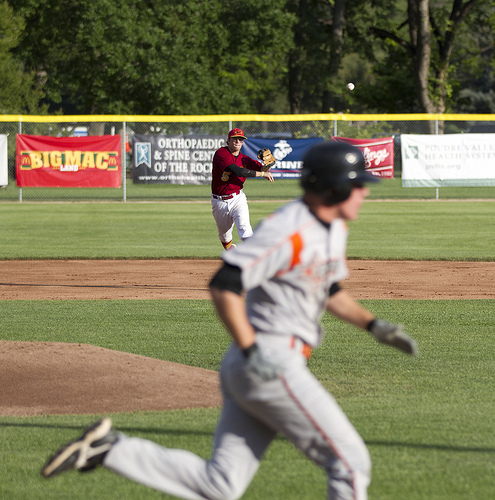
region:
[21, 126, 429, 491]
the baseball player is running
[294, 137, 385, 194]
the baseball player is wearing a baseball cap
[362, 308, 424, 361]
the man is wearing a glove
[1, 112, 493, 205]
a barrier behind the players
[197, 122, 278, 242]
the man is running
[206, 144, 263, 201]
the man is wearing a red shirt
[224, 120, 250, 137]
the man is wearing a red cap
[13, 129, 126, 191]
a Big Mac ad on the barrier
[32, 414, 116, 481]
the man is wearing a sneaker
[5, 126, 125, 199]
This is a banner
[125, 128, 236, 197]
This is a banner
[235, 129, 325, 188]
This is a banner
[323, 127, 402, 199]
This is a banner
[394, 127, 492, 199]
This is a banner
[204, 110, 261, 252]
This is a person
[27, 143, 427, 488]
This is a person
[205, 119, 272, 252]
This is a person running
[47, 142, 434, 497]
This is a person running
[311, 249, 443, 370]
This is a hand of a person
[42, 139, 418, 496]
a baseball player running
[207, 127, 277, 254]
a baseball player pitching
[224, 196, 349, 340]
a grey orange baseball jersey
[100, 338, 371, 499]
a grey orange pair of pants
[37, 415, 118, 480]
black and white cleated shoe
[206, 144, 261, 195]
a dark red baseball jersey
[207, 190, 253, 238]
a pair of white pants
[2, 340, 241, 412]
a pitcher's mound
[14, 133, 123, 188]
a large advertising banner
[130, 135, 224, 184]
a large advertising banner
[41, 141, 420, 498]
baseball player running on field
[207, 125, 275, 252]
baseball player in red jersey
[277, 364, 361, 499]
red pinstripe down pants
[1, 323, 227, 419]
dirt on pitchers mound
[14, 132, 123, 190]
red big mac banner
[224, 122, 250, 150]
red baseball cap on head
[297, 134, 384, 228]
black batters helmet on head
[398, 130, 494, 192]
white banner with green lettering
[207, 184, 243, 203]
red belt around waist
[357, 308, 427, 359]
batting glove on left hand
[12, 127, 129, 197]
This is a poster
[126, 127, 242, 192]
This is a poster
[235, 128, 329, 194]
This is a poster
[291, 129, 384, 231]
Head of a person